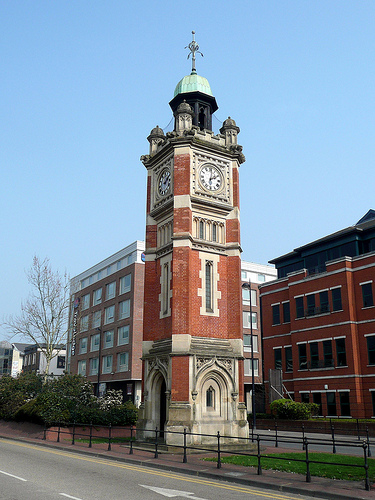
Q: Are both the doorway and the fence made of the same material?
A: No, the doorway is made of concrete and the fence is made of metal.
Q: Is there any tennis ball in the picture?
A: No, there are no tennis balls.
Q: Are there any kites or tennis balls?
A: No, there are no tennis balls or kites.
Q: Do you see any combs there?
A: No, there are no combs.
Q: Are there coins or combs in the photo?
A: No, there are no combs or coins.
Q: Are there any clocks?
A: Yes, there is a clock.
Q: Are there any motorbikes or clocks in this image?
A: Yes, there is a clock.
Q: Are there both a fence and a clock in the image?
A: Yes, there are both a clock and a fence.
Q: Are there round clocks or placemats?
A: Yes, there is a round clock.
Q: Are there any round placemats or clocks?
A: Yes, there is a round clock.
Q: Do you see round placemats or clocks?
A: Yes, there is a round clock.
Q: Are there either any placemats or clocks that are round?
A: Yes, the clock is round.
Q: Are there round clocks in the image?
A: Yes, there is a round clock.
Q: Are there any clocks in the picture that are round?
A: Yes, there is a clock that is round.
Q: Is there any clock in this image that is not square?
A: Yes, there is a round clock.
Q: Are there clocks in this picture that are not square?
A: Yes, there is a round clock.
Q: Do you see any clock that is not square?
A: Yes, there is a round clock.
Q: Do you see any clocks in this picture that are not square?
A: Yes, there is a round clock.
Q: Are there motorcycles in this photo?
A: No, there are no motorcycles.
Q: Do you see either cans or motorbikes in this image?
A: No, there are no motorbikes or cans.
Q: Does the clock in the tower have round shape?
A: Yes, the clock is round.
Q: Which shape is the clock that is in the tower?
A: The clock is round.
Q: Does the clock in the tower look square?
A: No, the clock is round.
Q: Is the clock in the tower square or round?
A: The clock is round.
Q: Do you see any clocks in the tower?
A: Yes, there is a clock in the tower.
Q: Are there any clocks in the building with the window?
A: Yes, there is a clock in the tower.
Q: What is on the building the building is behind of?
A: The clock is on the tower.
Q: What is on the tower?
A: The clock is on the tower.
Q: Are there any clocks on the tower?
A: Yes, there is a clock on the tower.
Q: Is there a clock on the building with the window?
A: Yes, there is a clock on the tower.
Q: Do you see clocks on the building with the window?
A: Yes, there is a clock on the tower.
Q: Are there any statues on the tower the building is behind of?
A: No, there is a clock on the tower.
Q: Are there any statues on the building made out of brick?
A: No, there is a clock on the tower.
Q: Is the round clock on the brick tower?
A: Yes, the clock is on the tower.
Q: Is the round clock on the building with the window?
A: Yes, the clock is on the tower.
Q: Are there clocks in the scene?
A: Yes, there is a clock.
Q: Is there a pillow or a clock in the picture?
A: Yes, there is a clock.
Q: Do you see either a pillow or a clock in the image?
A: Yes, there is a clock.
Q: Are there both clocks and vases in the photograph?
A: No, there is a clock but no vases.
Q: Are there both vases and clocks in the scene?
A: No, there is a clock but no vases.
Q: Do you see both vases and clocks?
A: No, there is a clock but no vases.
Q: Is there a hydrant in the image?
A: No, there are no fire hydrants.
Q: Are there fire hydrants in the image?
A: No, there are no fire hydrants.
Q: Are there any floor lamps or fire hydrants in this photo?
A: No, there are no fire hydrants or floor lamps.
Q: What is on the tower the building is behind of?
A: The clock is on the tower.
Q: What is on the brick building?
A: The clock is on the tower.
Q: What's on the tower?
A: The clock is on the tower.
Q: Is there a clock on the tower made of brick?
A: Yes, there is a clock on the tower.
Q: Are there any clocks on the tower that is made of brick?
A: Yes, there is a clock on the tower.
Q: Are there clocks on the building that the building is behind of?
A: Yes, there is a clock on the tower.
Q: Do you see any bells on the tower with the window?
A: No, there is a clock on the tower.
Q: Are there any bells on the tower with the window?
A: No, there is a clock on the tower.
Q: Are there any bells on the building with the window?
A: No, there is a clock on the tower.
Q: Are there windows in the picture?
A: Yes, there is a window.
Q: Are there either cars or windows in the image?
A: Yes, there is a window.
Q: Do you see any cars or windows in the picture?
A: Yes, there is a window.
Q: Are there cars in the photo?
A: No, there are no cars.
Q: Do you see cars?
A: No, there are no cars.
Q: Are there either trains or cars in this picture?
A: No, there are no cars or trains.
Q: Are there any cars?
A: No, there are no cars.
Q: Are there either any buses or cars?
A: No, there are no cars or buses.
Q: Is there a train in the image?
A: No, there are no trains.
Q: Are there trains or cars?
A: No, there are no trains or cars.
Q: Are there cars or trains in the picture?
A: No, there are no trains or cars.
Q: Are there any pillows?
A: No, there are no pillows.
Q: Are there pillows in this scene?
A: No, there are no pillows.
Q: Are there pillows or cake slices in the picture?
A: No, there are no pillows or cake slices.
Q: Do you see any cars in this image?
A: No, there are no cars.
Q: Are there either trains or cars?
A: No, there are no cars or trains.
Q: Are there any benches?
A: No, there are no benches.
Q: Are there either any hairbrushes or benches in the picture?
A: No, there are no benches or hairbrushes.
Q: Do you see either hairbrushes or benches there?
A: No, there are no benches or hairbrushes.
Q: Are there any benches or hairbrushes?
A: No, there are no benches or hairbrushes.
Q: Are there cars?
A: No, there are no cars.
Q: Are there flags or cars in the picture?
A: No, there are no cars or flags.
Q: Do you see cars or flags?
A: No, there are no cars or flags.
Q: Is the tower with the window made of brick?
A: Yes, the tower is made of brick.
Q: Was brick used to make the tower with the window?
A: Yes, the tower is made of brick.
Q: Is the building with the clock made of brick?
A: Yes, the tower is made of brick.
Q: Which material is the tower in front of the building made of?
A: The tower is made of brick.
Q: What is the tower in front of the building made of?
A: The tower is made of brick.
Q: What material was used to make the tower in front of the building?
A: The tower is made of brick.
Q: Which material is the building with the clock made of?
A: The tower is made of brick.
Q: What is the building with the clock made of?
A: The tower is made of brick.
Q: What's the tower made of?
A: The tower is made of brick.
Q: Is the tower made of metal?
A: No, the tower is made of brick.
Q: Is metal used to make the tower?
A: No, the tower is made of brick.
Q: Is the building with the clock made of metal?
A: No, the tower is made of brick.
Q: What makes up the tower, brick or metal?
A: The tower is made of brick.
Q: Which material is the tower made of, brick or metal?
A: The tower is made of brick.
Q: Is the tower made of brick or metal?
A: The tower is made of brick.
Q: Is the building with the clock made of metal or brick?
A: The tower is made of brick.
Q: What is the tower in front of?
A: The tower is in front of the building.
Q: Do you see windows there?
A: Yes, there is a window.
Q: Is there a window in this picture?
A: Yes, there is a window.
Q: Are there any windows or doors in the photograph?
A: Yes, there is a window.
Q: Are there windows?
A: Yes, there is a window.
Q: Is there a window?
A: Yes, there is a window.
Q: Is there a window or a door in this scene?
A: Yes, there is a window.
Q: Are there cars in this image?
A: No, there are no cars.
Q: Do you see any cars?
A: No, there are no cars.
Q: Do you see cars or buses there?
A: No, there are no cars or buses.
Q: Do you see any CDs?
A: No, there are no cds.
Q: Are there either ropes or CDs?
A: No, there are no CDs or ropes.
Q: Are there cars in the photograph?
A: No, there are no cars.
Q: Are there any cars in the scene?
A: No, there are no cars.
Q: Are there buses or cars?
A: No, there are no cars or buses.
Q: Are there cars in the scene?
A: No, there are no cars.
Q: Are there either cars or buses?
A: No, there are no cars or buses.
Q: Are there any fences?
A: Yes, there is a fence.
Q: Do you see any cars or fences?
A: Yes, there is a fence.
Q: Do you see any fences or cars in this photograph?
A: Yes, there is a fence.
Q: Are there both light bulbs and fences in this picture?
A: No, there is a fence but no light bulbs.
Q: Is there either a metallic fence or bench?
A: Yes, there is a metal fence.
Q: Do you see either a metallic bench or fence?
A: Yes, there is a metal fence.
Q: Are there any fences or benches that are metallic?
A: Yes, the fence is metallic.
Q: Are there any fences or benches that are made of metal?
A: Yes, the fence is made of metal.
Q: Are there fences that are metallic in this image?
A: Yes, there is a metal fence.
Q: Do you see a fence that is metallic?
A: Yes, there is a fence that is metallic.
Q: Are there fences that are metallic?
A: Yes, there is a fence that is metallic.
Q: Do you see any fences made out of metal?
A: Yes, there is a fence that is made of metal.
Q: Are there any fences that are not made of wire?
A: Yes, there is a fence that is made of metal.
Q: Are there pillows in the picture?
A: No, there are no pillows.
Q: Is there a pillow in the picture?
A: No, there are no pillows.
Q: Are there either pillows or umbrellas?
A: No, there are no pillows or umbrellas.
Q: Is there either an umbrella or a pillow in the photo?
A: No, there are no pillows or umbrellas.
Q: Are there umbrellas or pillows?
A: No, there are no pillows or umbrellas.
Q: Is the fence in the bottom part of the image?
A: Yes, the fence is in the bottom of the image.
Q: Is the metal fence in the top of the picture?
A: No, the fence is in the bottom of the image.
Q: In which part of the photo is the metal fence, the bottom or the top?
A: The fence is in the bottom of the image.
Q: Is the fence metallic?
A: Yes, the fence is metallic.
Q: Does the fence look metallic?
A: Yes, the fence is metallic.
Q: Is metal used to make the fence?
A: Yes, the fence is made of metal.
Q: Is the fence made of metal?
A: Yes, the fence is made of metal.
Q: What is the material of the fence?
A: The fence is made of metal.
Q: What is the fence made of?
A: The fence is made of metal.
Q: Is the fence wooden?
A: No, the fence is metallic.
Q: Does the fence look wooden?
A: No, the fence is metallic.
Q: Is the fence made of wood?
A: No, the fence is made of metal.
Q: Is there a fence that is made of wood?
A: No, there is a fence but it is made of metal.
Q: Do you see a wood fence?
A: No, there is a fence but it is made of metal.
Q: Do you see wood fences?
A: No, there is a fence but it is made of metal.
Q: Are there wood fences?
A: No, there is a fence but it is made of metal.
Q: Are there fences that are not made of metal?
A: No, there is a fence but it is made of metal.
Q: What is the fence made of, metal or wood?
A: The fence is made of metal.